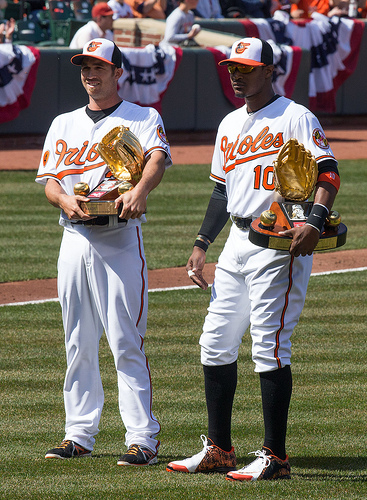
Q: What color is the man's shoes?
A: Blue.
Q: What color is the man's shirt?
A: White.